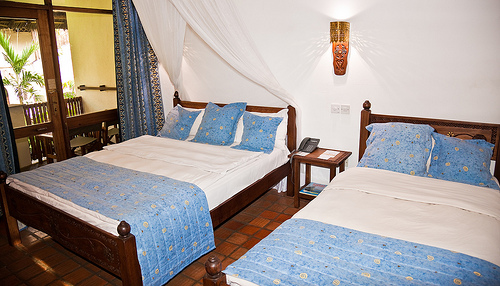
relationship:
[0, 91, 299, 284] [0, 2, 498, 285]
bed in room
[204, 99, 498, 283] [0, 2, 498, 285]
bed in room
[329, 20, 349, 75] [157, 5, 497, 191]
light on wall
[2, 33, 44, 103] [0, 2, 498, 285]
tree outside room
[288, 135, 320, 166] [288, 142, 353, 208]
phone on nightstand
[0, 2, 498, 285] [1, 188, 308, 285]
room has floor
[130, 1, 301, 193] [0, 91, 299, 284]
net over bed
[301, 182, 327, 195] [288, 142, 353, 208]
magazine on nightstand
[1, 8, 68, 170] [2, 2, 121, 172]
door shows outside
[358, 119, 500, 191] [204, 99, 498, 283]
pillows on bed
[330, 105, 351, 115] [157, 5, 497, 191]
switch on wall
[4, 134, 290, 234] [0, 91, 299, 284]
sheet on bed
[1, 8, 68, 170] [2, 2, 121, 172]
door to outside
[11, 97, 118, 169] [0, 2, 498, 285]
patio outside room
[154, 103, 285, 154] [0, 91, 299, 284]
pillows on bed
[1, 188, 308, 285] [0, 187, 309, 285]
floor has tile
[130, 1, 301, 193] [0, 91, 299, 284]
net hand over bed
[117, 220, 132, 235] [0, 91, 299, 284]
knob on bed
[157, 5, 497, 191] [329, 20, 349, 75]
wall has light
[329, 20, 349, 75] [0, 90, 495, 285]
light between beds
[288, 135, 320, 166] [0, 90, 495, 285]
phone between beds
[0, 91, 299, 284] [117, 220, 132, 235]
bed has knob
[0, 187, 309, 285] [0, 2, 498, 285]
tile in room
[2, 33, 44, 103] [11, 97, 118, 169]
tree outside patio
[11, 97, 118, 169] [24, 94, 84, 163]
patio has railing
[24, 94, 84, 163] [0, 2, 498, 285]
railing outside room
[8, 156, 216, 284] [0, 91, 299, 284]
bedspread at foot of bed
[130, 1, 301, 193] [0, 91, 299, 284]
net at head of bed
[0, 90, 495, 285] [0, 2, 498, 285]
beds in room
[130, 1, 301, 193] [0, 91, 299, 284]
net behind bed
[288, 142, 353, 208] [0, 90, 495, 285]
nightstand between beds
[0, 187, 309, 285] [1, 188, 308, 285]
tile on floor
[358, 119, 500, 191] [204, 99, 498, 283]
pillows across bed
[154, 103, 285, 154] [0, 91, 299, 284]
pillows across bed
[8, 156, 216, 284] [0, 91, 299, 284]
bedspread across bed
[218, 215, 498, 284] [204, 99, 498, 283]
bedspread across bed